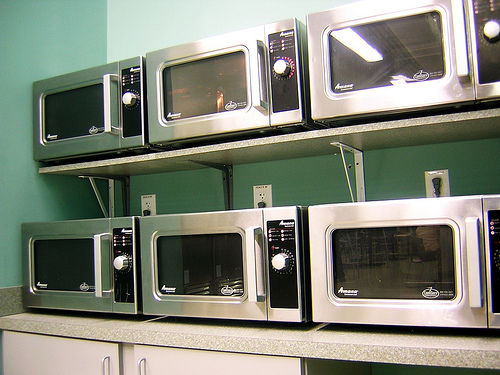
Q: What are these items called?
A: Microwaves.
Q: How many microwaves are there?
A: Six.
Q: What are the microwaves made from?
A: Metal.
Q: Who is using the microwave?
A: No one.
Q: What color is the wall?
A: Green.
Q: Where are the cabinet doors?
A: Under the microwaves.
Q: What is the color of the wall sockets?
A: White.